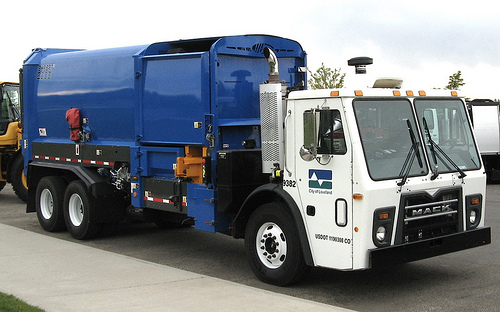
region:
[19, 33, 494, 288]
a commercial blue and white truck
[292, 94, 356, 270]
a truck passenger door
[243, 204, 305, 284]
a black front passenger tire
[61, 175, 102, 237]
a black rear passenger tire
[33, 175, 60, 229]
a black rear passenger tire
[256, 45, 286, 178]
a truck exhaust pipe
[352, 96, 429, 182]
a truck front windshield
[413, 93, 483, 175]
a truck front windshield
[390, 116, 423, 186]
a black windshield wiper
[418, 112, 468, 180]
a black windshield wiper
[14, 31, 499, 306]
a garbage truck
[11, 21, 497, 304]
a garbage truck on the road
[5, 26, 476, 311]
blue and white garbage truck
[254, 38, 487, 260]
a white truck cab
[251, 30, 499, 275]
a small white truck cab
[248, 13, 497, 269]
a truck cab on the road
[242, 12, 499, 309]
truck cab on the road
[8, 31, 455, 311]
a big truck on the road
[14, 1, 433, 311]
Picture taken outdoors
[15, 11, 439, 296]
Picture taken during the day time.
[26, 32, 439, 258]
A large utility truck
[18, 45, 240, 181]
The back of the truck is blue.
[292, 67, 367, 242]
The cab of the truck is mostly white.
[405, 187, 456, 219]
It is a MACK truck.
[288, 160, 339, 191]
The company's logo on the door.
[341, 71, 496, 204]
Large front windows.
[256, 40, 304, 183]
Muffler is next to the cab.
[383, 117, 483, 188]
The wipers are not moving.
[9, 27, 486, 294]
a trash truck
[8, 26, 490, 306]
a garbage truck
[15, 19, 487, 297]
a white and blue garbage truck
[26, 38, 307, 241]
a blue garbage compactor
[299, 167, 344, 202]
a blue and green logo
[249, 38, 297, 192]
a large exhaust pipe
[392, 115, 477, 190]
black windshield wipers on a truck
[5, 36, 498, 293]
a truck parked on the side of the road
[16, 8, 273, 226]
a blue truck trailer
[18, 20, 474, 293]
mack truck on road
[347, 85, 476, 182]
window on front of truck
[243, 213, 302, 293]
tire on the truck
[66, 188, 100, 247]
tire on the truck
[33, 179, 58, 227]
tire on the truck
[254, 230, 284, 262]
wheel of the truck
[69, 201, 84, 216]
wheel of the truck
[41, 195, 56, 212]
wheel of the truck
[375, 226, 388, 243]
head light on the truck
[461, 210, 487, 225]
head light on the truck